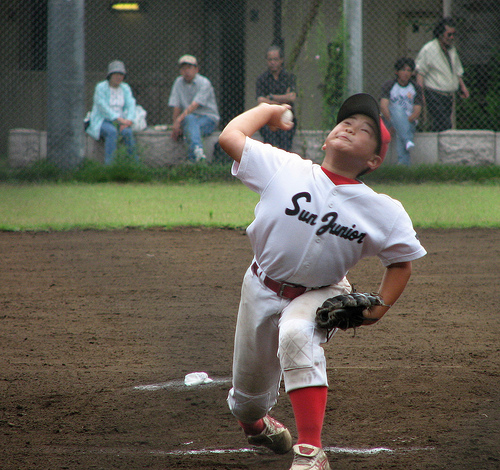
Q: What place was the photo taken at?
A: It was taken at the field.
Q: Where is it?
A: This is at the field.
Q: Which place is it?
A: It is a field.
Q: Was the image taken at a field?
A: Yes, it was taken in a field.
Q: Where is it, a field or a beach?
A: It is a field.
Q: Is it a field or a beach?
A: It is a field.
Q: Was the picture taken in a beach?
A: No, the picture was taken in a field.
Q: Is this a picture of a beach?
A: No, the picture is showing a field.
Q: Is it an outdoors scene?
A: Yes, it is outdoors.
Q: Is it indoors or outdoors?
A: It is outdoors.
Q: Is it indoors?
A: No, it is outdoors.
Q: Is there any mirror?
A: No, there are no mirrors.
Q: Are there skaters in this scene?
A: No, there are no skaters.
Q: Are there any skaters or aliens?
A: No, there are no skaters or aliens.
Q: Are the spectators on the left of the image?
A: Yes, the spectators are on the left of the image.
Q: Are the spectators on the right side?
A: No, the spectators are on the left of the image.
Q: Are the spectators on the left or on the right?
A: The spectators are on the left of the image.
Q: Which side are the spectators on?
A: The spectators are on the left of the image.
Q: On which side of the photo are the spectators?
A: The spectators are on the left of the image.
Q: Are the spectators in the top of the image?
A: Yes, the spectators are in the top of the image.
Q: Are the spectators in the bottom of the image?
A: No, the spectators are in the top of the image.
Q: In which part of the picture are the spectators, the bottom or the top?
A: The spectators are in the top of the image.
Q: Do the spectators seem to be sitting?
A: Yes, the spectators are sitting.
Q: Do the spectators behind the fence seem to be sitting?
A: Yes, the spectators are sitting.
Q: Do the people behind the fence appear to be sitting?
A: Yes, the spectators are sitting.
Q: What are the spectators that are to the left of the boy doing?
A: The spectators are sitting.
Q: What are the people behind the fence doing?
A: The spectators are sitting.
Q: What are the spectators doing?
A: The spectators are sitting.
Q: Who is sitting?
A: The spectators are sitting.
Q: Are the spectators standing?
A: No, the spectators are sitting.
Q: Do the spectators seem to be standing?
A: No, the spectators are sitting.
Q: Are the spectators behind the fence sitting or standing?
A: The spectators are sitting.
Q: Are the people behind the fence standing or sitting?
A: The spectators are sitting.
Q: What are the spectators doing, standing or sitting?
A: The spectators are sitting.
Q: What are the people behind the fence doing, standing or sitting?
A: The spectators are sitting.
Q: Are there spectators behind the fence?
A: Yes, there are spectators behind the fence.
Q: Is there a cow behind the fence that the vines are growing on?
A: No, there are spectators behind the fence.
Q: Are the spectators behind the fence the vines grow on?
A: Yes, the spectators are behind the fence.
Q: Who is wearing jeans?
A: The spectators are wearing jeans.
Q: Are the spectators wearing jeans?
A: Yes, the spectators are wearing jeans.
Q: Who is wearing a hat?
A: The spectators are wearing a hat.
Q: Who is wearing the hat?
A: The spectators are wearing a hat.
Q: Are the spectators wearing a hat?
A: Yes, the spectators are wearing a hat.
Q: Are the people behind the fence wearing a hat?
A: Yes, the spectators are wearing a hat.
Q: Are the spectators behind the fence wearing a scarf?
A: No, the spectators are wearing a hat.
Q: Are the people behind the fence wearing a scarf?
A: No, the spectators are wearing a hat.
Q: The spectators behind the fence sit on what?
A: The spectators sit on the wall.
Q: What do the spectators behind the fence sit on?
A: The spectators sit on the wall.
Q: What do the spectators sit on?
A: The spectators sit on the wall.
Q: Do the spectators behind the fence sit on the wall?
A: Yes, the spectators sit on the wall.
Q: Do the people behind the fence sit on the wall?
A: Yes, the spectators sit on the wall.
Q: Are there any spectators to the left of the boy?
A: Yes, there are spectators to the left of the boy.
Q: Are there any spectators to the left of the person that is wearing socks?
A: Yes, there are spectators to the left of the boy.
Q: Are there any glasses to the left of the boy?
A: No, there are spectators to the left of the boy.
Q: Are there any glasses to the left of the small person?
A: No, there are spectators to the left of the boy.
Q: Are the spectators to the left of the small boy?
A: Yes, the spectators are to the left of the boy.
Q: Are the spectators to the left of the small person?
A: Yes, the spectators are to the left of the boy.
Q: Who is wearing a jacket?
A: The spectators are wearing a jacket.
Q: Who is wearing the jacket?
A: The spectators are wearing a jacket.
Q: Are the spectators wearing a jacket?
A: Yes, the spectators are wearing a jacket.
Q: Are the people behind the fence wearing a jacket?
A: Yes, the spectators are wearing a jacket.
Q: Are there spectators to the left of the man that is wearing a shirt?
A: Yes, there are spectators to the left of the man.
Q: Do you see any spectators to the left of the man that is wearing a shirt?
A: Yes, there are spectators to the left of the man.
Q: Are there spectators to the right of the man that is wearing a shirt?
A: No, the spectators are to the left of the man.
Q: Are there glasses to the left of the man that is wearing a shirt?
A: No, there are spectators to the left of the man.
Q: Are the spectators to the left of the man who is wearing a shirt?
A: Yes, the spectators are to the left of the man.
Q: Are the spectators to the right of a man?
A: No, the spectators are to the left of a man.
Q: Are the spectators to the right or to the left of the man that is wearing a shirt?
A: The spectators are to the left of the man.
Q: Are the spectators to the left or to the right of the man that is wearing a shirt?
A: The spectators are to the left of the man.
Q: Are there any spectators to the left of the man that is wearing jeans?
A: Yes, there are spectators to the left of the man.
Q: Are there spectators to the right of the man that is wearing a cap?
A: No, the spectators are to the left of the man.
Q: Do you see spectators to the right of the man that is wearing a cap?
A: No, the spectators are to the left of the man.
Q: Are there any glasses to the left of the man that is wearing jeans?
A: No, there are spectators to the left of the man.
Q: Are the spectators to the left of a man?
A: Yes, the spectators are to the left of a man.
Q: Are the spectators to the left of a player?
A: No, the spectators are to the left of a man.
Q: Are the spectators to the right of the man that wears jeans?
A: No, the spectators are to the left of the man.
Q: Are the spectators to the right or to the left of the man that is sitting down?
A: The spectators are to the left of the man.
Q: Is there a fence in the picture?
A: Yes, there is a fence.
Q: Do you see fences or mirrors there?
A: Yes, there is a fence.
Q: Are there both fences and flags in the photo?
A: No, there is a fence but no flags.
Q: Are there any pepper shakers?
A: No, there are no pepper shakers.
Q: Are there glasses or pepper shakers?
A: No, there are no pepper shakers or glasses.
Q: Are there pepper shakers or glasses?
A: No, there are no pepper shakers or glasses.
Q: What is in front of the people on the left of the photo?
A: The fence is in front of the spectators.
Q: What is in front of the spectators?
A: The fence is in front of the spectators.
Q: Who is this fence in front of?
A: The fence is in front of the spectators.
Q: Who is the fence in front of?
A: The fence is in front of the spectators.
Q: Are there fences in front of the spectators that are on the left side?
A: Yes, there is a fence in front of the spectators.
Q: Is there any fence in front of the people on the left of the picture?
A: Yes, there is a fence in front of the spectators.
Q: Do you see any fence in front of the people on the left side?
A: Yes, there is a fence in front of the spectators.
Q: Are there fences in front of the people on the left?
A: Yes, there is a fence in front of the spectators.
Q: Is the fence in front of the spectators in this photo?
A: Yes, the fence is in front of the spectators.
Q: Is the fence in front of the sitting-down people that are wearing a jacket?
A: Yes, the fence is in front of the spectators.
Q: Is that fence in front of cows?
A: No, the fence is in front of the spectators.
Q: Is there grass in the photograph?
A: Yes, there is grass.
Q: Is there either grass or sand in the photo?
A: Yes, there is grass.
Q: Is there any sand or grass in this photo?
A: Yes, there is grass.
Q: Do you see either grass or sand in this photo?
A: Yes, there is grass.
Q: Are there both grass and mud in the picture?
A: No, there is grass but no mud.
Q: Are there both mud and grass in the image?
A: No, there is grass but no mud.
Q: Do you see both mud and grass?
A: No, there is grass but no mud.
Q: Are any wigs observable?
A: No, there are no wigs.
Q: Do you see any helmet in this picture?
A: No, there are no helmets.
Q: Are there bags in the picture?
A: No, there are no bags.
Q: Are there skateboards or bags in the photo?
A: No, there are no bags or skateboards.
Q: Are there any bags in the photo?
A: No, there are no bags.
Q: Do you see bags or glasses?
A: No, there are no bags or glasses.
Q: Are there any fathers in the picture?
A: No, there are no fathers.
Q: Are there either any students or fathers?
A: No, there are no fathers or students.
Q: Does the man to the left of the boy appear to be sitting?
A: Yes, the man is sitting.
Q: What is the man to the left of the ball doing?
A: The man is sitting.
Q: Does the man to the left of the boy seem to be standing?
A: No, the man is sitting.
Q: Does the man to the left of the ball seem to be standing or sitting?
A: The man is sitting.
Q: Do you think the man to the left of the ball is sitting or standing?
A: The man is sitting.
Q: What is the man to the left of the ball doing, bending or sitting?
A: The man is sitting.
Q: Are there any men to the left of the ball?
A: Yes, there is a man to the left of the ball.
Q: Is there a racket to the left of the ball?
A: No, there is a man to the left of the ball.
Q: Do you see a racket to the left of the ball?
A: No, there is a man to the left of the ball.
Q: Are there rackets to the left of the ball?
A: No, there is a man to the left of the ball.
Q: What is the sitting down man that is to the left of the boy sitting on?
A: The man is sitting on the wall.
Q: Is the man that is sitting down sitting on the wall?
A: Yes, the man is sitting on the wall.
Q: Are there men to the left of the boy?
A: Yes, there is a man to the left of the boy.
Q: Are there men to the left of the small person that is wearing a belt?
A: Yes, there is a man to the left of the boy.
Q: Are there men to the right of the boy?
A: No, the man is to the left of the boy.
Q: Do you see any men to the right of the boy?
A: No, the man is to the left of the boy.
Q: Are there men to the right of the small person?
A: No, the man is to the left of the boy.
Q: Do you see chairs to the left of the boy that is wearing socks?
A: No, there is a man to the left of the boy.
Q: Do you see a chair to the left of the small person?
A: No, there is a man to the left of the boy.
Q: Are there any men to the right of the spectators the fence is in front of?
A: Yes, there is a man to the right of the spectators.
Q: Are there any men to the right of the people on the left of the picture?
A: Yes, there is a man to the right of the spectators.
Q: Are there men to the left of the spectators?
A: No, the man is to the right of the spectators.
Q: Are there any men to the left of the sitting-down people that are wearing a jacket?
A: No, the man is to the right of the spectators.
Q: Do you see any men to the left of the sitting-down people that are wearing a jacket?
A: No, the man is to the right of the spectators.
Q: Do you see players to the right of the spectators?
A: No, there is a man to the right of the spectators.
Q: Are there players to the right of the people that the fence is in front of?
A: No, there is a man to the right of the spectators.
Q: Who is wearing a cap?
A: The man is wearing a cap.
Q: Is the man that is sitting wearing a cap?
A: Yes, the man is wearing a cap.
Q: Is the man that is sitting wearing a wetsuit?
A: No, the man is wearing a cap.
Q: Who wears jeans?
A: The man wears jeans.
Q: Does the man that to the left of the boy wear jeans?
A: Yes, the man wears jeans.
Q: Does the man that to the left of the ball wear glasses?
A: No, the man wears jeans.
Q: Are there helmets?
A: No, there are no helmets.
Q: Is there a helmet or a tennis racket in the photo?
A: No, there are no helmets or rackets.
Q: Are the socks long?
A: Yes, the socks are long.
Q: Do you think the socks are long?
A: Yes, the socks are long.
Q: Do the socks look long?
A: Yes, the socks are long.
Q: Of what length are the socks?
A: The socks are long.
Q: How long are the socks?
A: The socks are long.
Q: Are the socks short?
A: No, the socks are long.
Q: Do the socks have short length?
A: No, the socks are long.